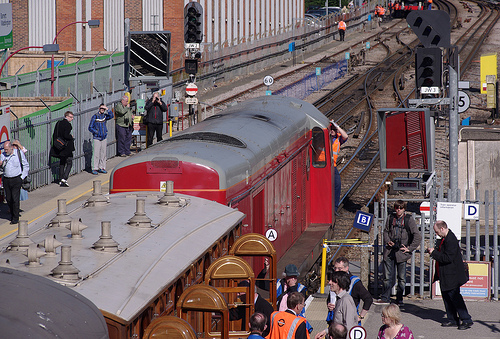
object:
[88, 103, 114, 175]
man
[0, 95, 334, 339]
train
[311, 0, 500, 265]
track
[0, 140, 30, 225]
people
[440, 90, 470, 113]
sign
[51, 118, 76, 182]
suit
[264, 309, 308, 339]
vest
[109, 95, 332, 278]
engine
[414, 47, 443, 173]
signal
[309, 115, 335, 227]
door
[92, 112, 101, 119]
shoulder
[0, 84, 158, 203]
fence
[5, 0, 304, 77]
building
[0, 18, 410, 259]
platform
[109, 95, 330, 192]
roof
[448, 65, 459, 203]
pole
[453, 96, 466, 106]
letter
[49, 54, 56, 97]
pole